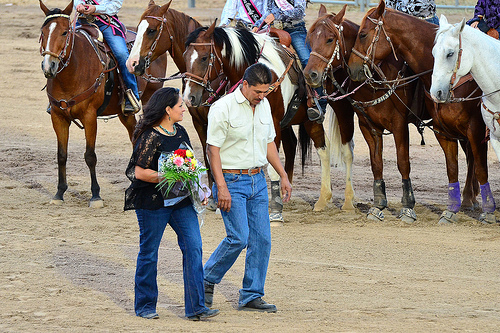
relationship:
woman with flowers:
[120, 86, 218, 323] [155, 151, 210, 217]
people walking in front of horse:
[125, 59, 287, 319] [431, 13, 500, 171]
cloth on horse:
[448, 177, 491, 206] [39, 4, 432, 228]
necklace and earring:
[155, 120, 182, 139] [163, 109, 174, 124]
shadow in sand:
[40, 241, 179, 319] [7, 58, 499, 329]